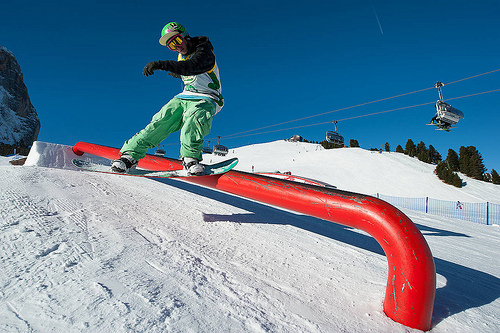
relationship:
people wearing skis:
[433, 105, 464, 128] [420, 117, 455, 138]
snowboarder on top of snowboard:
[109, 20, 226, 177] [122, 152, 242, 180]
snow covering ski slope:
[86, 235, 177, 291] [2, 140, 484, 330]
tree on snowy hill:
[346, 136, 362, 148] [333, 153, 401, 190]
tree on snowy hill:
[427, 142, 441, 164] [333, 153, 401, 190]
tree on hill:
[346, 136, 362, 148] [200, 137, 495, 332]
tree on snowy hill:
[346, 136, 362, 148] [0, 138, 499, 333]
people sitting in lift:
[432, 115, 456, 133] [425, 81, 462, 128]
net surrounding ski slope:
[405, 192, 497, 223] [369, 167, 498, 212]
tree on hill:
[346, 136, 362, 148] [216, 139, 498, 214]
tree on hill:
[346, 136, 362, 148] [203, 139, 498, 208]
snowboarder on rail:
[107, 17, 233, 181] [235, 168, 440, 326]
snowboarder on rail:
[109, 20, 226, 177] [72, 140, 438, 332]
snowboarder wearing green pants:
[109, 20, 226, 177] [115, 97, 213, 166]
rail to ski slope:
[72, 140, 438, 332] [2, 140, 484, 330]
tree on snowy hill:
[382, 140, 391, 155] [0, 138, 499, 333]